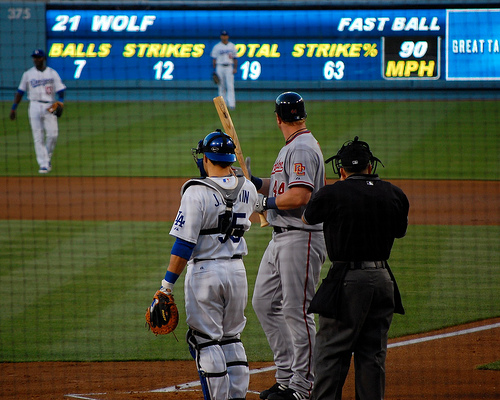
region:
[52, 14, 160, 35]
21 Wolf on Scoreboard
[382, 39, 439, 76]
Sign says 90 MPH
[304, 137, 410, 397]
Umpire standing behind batter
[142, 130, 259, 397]
Catcher standing next to umpire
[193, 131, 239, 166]
Catcher wearing a blue cap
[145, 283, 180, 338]
Catcher wearing mitt on left hand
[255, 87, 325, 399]
Batter standing in front of umpire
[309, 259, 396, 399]
Umpire wearing dark grey pants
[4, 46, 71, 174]
Baseball player walking in the field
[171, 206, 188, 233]
Catcher has LA on his shirt sleeve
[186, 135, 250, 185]
the head of a man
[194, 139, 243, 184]
the neck of a man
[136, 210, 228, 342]
the arm of a man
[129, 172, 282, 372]
a man wearing a glove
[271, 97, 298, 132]
the ear of a man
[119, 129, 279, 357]
a man wearing a uniform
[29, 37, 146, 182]
a man in the out field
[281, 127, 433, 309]
a man wearing a black shirt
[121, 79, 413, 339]
men playing baseball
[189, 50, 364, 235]
a man holding a bat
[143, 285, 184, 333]
he is wearing a glove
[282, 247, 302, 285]
the pants are gray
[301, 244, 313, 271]
the stripe is red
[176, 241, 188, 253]
the shirt is blue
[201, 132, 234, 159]
the helmet is blue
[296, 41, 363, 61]
the word is yellow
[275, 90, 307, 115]
the helmet is black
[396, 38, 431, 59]
the number is white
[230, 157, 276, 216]
he is holding the bat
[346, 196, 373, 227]
the shirt is black